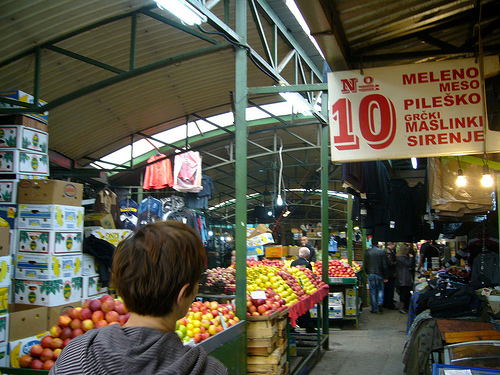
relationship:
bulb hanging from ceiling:
[455, 176, 467, 187] [70, 0, 325, 138]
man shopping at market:
[399, 270, 457, 368] [0, 0, 500, 375]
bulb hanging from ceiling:
[455, 176, 467, 187] [0, 0, 497, 214]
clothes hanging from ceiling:
[142, 153, 173, 189] [0, 0, 497, 214]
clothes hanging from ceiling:
[142, 153, 173, 189] [0, 0, 498, 167]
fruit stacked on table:
[244, 261, 329, 317] [14, 286, 244, 374]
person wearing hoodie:
[45, 222, 225, 374] [46, 324, 230, 374]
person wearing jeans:
[45, 222, 225, 374] [368, 272, 386, 308]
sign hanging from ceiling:
[326, 59, 489, 169] [12, 6, 394, 198]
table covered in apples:
[269, 283, 330, 318] [278, 274, 302, 298]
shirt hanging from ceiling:
[167, 144, 205, 200] [55, 41, 245, 170]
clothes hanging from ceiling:
[142, 153, 173, 189] [87, 37, 289, 104]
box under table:
[246, 318, 277, 356] [241, 278, 331, 325]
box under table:
[239, 350, 288, 373] [241, 278, 331, 325]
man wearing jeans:
[358, 232, 398, 315] [362, 267, 389, 308]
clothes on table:
[424, 277, 476, 319] [411, 269, 497, 374]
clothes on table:
[142, 153, 173, 189] [411, 269, 497, 374]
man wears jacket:
[364, 237, 390, 313] [366, 248, 386, 278]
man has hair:
[296, 233, 316, 261] [298, 250, 303, 254]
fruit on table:
[244, 261, 329, 317] [227, 278, 332, 368]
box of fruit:
[2, 117, 48, 153] [64, 301, 107, 323]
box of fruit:
[14, 251, 84, 280] [64, 301, 107, 323]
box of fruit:
[16, 177, 83, 202] [64, 301, 107, 323]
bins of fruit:
[14, 203, 85, 232] [64, 301, 107, 323]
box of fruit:
[13, 280, 87, 307] [64, 301, 107, 323]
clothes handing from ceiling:
[142, 153, 173, 189] [163, 39, 229, 86]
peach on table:
[258, 306, 266, 313] [247, 275, 333, 334]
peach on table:
[266, 301, 273, 309] [247, 275, 333, 334]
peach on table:
[249, 312, 260, 317] [247, 275, 333, 334]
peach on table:
[245, 298, 250, 306] [247, 275, 333, 334]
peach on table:
[272, 295, 281, 302] [247, 275, 333, 334]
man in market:
[364, 237, 390, 313] [7, 5, 492, 369]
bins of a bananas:
[14, 203, 85, 232] [50, 255, 82, 275]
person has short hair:
[45, 222, 225, 374] [112, 222, 207, 322]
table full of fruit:
[269, 282, 346, 314] [188, 246, 329, 308]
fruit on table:
[188, 246, 329, 308] [269, 282, 346, 314]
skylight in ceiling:
[74, 94, 324, 181] [0, 0, 497, 214]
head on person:
[102, 218, 201, 310] [45, 222, 225, 374]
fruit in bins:
[244, 261, 329, 317] [16, 250, 356, 373]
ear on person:
[175, 280, 192, 306] [45, 222, 225, 374]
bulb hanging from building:
[455, 176, 467, 187] [0, 0, 500, 182]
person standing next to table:
[17, 221, 242, 372] [9, 279, 251, 373]